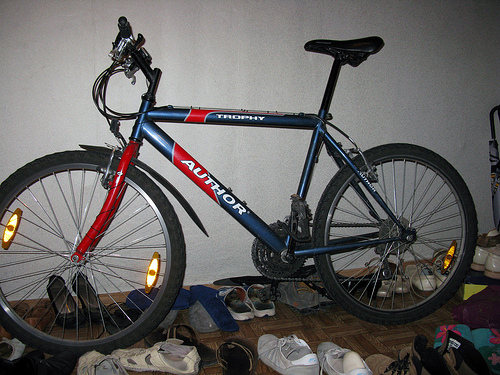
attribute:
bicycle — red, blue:
[1, 16, 480, 355]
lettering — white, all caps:
[179, 157, 246, 218]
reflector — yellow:
[143, 249, 161, 293]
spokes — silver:
[53, 169, 99, 244]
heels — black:
[46, 271, 106, 327]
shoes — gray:
[256, 327, 371, 374]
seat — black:
[305, 34, 386, 69]